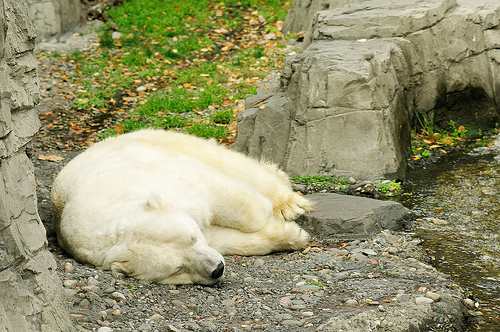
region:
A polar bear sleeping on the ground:
[48, 124, 317, 287]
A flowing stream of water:
[400, 122, 499, 330]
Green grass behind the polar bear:
[106, 4, 210, 58]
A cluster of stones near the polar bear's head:
[63, 278, 126, 312]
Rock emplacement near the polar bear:
[236, 2, 498, 187]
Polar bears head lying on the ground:
[108, 191, 230, 288]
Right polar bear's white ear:
[143, 190, 167, 210]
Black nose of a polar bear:
[201, 255, 231, 282]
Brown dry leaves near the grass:
[214, 23, 286, 60]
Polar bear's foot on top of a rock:
[267, 193, 314, 222]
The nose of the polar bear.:
[211, 260, 222, 273]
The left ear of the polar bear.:
[110, 260, 130, 276]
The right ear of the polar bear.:
[145, 190, 160, 205]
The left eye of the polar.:
[167, 260, 187, 273]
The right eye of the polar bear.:
[191, 230, 201, 242]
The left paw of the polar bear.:
[275, 220, 306, 245]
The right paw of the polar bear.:
[268, 197, 309, 214]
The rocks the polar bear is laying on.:
[61, 241, 416, 323]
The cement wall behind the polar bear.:
[4, 0, 56, 328]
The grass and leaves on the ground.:
[72, 12, 236, 125]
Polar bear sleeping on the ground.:
[50, 119, 310, 284]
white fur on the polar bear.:
[47, 122, 313, 292]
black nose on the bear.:
[206, 257, 228, 282]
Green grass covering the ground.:
[47, 0, 288, 147]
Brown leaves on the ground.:
[47, 3, 283, 137]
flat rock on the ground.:
[38, 144, 478, 330]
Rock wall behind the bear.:
[0, 0, 79, 330]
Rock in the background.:
[237, 0, 498, 187]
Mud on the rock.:
[425, 83, 493, 125]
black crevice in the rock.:
[465, 42, 498, 60]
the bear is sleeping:
[22, 26, 383, 301]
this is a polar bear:
[23, 67, 358, 322]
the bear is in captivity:
[18, 54, 300, 312]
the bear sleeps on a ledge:
[21, 12, 461, 317]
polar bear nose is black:
[46, 78, 351, 277]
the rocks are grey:
[21, 61, 405, 326]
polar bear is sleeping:
[6, 29, 386, 306]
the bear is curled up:
[20, 82, 354, 321]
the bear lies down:
[5, 84, 354, 291]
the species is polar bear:
[33, 80, 386, 327]